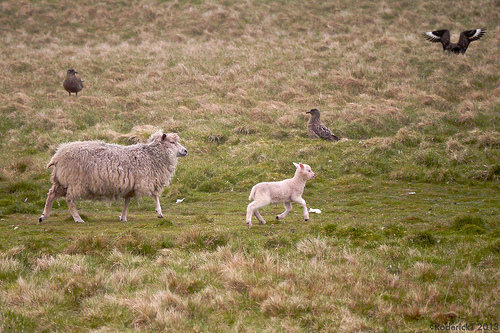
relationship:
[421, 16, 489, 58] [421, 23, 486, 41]
bird extending wings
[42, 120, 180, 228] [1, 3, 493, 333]
sheep walking in field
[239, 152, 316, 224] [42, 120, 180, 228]
lamb running ahead of sheep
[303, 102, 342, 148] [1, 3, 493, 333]
bird standing in field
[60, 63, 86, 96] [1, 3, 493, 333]
bird standing in field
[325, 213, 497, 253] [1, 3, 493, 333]
weeds growing in field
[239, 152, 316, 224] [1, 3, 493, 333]
lamb in field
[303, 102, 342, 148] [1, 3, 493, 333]
bird in field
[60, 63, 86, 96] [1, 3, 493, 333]
bird in field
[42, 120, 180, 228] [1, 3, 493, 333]
sheep walking on field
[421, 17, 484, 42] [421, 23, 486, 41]
marks on wings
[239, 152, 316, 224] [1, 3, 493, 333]
lamb running through field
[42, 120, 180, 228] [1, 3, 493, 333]
sheep walking through field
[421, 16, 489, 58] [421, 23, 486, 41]
bird with wings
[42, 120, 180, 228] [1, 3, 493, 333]
sheep in field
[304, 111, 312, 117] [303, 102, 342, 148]
beak of bird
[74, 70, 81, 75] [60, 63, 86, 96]
beak of bird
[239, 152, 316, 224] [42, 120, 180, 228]
lamb traveling with sheep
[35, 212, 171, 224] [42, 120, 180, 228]
hooves of sheep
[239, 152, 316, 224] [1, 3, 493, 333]
lamb running in field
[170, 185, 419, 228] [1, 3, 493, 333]
trash on field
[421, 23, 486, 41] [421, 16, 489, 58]
wings of bird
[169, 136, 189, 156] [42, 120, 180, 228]
face of sheep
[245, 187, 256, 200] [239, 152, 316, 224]
tail of lamb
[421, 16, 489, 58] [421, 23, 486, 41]
bird flapping its wings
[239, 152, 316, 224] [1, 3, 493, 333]
lamb walking on field